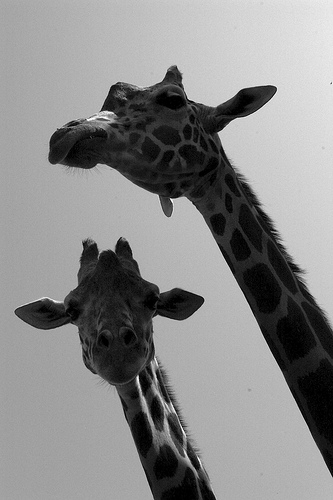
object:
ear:
[209, 84, 277, 132]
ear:
[155, 286, 203, 321]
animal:
[41, 63, 333, 479]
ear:
[13, 294, 71, 330]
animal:
[13, 236, 217, 499]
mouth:
[93, 344, 150, 388]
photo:
[0, 0, 332, 498]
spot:
[274, 295, 318, 363]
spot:
[243, 262, 282, 316]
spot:
[227, 227, 252, 263]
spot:
[265, 230, 301, 295]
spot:
[238, 202, 264, 257]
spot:
[149, 390, 164, 431]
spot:
[166, 412, 185, 460]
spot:
[151, 440, 176, 484]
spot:
[131, 413, 153, 457]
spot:
[184, 441, 200, 472]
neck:
[193, 164, 332, 476]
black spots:
[150, 122, 181, 149]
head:
[45, 64, 279, 218]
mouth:
[40, 130, 105, 173]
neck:
[109, 361, 220, 499]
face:
[47, 59, 184, 193]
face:
[63, 249, 159, 387]